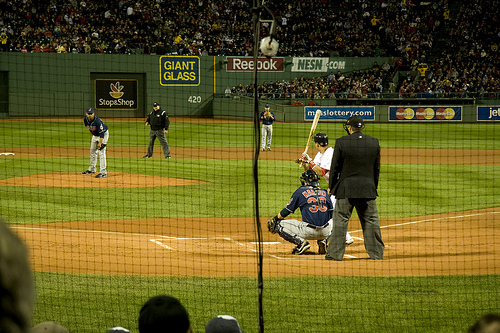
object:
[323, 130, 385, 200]
jacket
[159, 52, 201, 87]
ad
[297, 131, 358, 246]
batter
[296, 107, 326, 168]
bat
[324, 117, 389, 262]
umpire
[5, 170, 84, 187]
red clay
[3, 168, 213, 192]
mound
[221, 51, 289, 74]
reebok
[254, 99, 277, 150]
outfielder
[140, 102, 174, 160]
umpire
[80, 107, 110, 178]
pitcher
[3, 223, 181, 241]
line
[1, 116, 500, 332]
field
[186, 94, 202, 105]
number 420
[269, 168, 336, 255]
catcher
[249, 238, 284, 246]
homeplate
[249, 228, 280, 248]
homebase